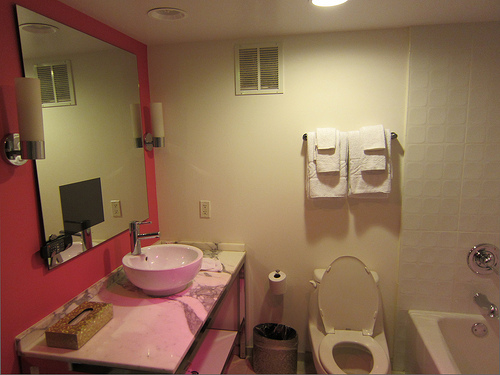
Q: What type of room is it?
A: It is a bathroom.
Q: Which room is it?
A: It is a bathroom.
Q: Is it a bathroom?
A: Yes, it is a bathroom.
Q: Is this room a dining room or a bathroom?
A: It is a bathroom.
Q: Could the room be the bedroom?
A: No, it is the bathroom.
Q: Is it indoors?
A: Yes, it is indoors.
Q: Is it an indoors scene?
A: Yes, it is indoors.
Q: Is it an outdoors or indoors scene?
A: It is indoors.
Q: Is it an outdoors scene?
A: No, it is indoors.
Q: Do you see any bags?
A: No, there are no bags.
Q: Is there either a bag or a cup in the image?
A: No, there are no bags or cups.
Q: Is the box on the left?
A: Yes, the box is on the left of the image.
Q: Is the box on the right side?
A: No, the box is on the left of the image.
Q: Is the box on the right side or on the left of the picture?
A: The box is on the left of the image.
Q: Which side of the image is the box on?
A: The box is on the left of the image.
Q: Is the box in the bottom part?
A: Yes, the box is in the bottom of the image.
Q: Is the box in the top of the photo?
A: No, the box is in the bottom of the image.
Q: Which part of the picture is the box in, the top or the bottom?
A: The box is in the bottom of the image.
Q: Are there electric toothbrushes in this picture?
A: No, there are no electric toothbrushes.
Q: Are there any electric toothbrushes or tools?
A: No, there are no electric toothbrushes or tools.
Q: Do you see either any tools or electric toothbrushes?
A: No, there are no electric toothbrushes or tools.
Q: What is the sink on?
A: The sink is on the counter.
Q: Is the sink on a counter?
A: Yes, the sink is on a counter.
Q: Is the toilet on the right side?
A: Yes, the toilet is on the right of the image.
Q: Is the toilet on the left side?
A: No, the toilet is on the right of the image.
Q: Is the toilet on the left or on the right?
A: The toilet is on the right of the image.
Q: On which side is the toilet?
A: The toilet is on the right of the image.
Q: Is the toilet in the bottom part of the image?
A: Yes, the toilet is in the bottom of the image.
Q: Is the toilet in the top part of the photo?
A: No, the toilet is in the bottom of the image.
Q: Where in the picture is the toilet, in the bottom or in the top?
A: The toilet is in the bottom of the image.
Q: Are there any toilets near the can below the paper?
A: Yes, there is a toilet near the can.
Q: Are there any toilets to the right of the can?
A: Yes, there is a toilet to the right of the can.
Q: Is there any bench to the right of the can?
A: No, there is a toilet to the right of the can.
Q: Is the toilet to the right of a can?
A: Yes, the toilet is to the right of a can.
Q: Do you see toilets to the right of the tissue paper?
A: Yes, there is a toilet to the right of the tissue paper.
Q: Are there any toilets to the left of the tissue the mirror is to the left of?
A: No, the toilet is to the right of the tissue paper.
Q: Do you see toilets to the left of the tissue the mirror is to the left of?
A: No, the toilet is to the right of the tissue paper.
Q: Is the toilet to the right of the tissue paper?
A: Yes, the toilet is to the right of the tissue paper.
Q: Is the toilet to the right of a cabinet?
A: No, the toilet is to the right of the tissue paper.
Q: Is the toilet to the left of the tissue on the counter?
A: No, the toilet is to the right of the tissue.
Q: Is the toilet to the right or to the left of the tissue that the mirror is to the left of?
A: The toilet is to the right of the tissue paper.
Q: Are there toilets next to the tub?
A: Yes, there is a toilet next to the tub.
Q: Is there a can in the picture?
A: Yes, there is a can.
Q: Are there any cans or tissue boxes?
A: Yes, there is a can.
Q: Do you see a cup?
A: No, there are no cups.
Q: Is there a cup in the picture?
A: No, there are no cups.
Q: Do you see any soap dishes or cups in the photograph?
A: No, there are no cups or soap dishes.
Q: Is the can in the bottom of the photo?
A: Yes, the can is in the bottom of the image.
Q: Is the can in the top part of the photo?
A: No, the can is in the bottom of the image.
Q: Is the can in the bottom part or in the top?
A: The can is in the bottom of the image.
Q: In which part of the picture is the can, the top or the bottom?
A: The can is in the bottom of the image.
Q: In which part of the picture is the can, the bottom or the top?
A: The can is in the bottom of the image.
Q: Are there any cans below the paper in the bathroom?
A: Yes, there is a can below the paper.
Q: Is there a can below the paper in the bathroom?
A: Yes, there is a can below the paper.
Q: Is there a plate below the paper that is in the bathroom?
A: No, there is a can below the paper.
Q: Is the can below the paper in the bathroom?
A: Yes, the can is below the paper.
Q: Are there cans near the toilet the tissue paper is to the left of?
A: Yes, there is a can near the toilet.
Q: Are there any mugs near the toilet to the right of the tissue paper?
A: No, there is a can near the toilet.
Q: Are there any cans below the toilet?
A: Yes, there is a can below the toilet.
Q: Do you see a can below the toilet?
A: Yes, there is a can below the toilet.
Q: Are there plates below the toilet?
A: No, there is a can below the toilet.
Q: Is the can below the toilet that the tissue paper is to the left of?
A: Yes, the can is below the toilet.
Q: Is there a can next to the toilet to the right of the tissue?
A: Yes, there is a can next to the toilet.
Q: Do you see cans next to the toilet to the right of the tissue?
A: Yes, there is a can next to the toilet.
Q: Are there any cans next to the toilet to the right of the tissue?
A: Yes, there is a can next to the toilet.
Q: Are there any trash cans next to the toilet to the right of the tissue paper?
A: No, there is a can next to the toilet.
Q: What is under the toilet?
A: The can is under the toilet.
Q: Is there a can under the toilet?
A: Yes, there is a can under the toilet.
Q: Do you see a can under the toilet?
A: Yes, there is a can under the toilet.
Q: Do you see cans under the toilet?
A: Yes, there is a can under the toilet.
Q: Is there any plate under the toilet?
A: No, there is a can under the toilet.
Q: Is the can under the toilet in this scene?
A: Yes, the can is under the toilet.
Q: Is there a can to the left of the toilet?
A: Yes, there is a can to the left of the toilet.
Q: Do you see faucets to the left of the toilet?
A: No, there is a can to the left of the toilet.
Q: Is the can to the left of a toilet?
A: Yes, the can is to the left of a toilet.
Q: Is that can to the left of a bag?
A: No, the can is to the left of a toilet.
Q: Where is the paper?
A: The paper is in the bathroom.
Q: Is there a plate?
A: No, there are no plates.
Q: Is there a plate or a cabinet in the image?
A: No, there are no plates or cabinets.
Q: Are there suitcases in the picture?
A: No, there are no suitcases.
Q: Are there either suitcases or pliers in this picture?
A: No, there are no suitcases or pliers.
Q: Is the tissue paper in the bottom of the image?
A: Yes, the tissue paper is in the bottom of the image.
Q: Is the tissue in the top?
A: No, the tissue is in the bottom of the image.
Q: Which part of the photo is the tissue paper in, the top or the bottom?
A: The tissue paper is in the bottom of the image.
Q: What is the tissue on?
A: The tissue is on the counter.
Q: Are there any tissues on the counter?
A: Yes, there is a tissue on the counter.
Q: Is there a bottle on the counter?
A: No, there is a tissue on the counter.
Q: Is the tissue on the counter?
A: Yes, the tissue is on the counter.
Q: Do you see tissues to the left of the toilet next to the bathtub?
A: Yes, there is a tissue to the left of the toilet.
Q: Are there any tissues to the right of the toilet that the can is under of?
A: No, the tissue is to the left of the toilet.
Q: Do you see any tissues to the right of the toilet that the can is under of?
A: No, the tissue is to the left of the toilet.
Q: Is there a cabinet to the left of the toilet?
A: No, there is a tissue to the left of the toilet.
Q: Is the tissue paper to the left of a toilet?
A: Yes, the tissue paper is to the left of a toilet.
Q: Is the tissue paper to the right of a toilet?
A: No, the tissue paper is to the left of a toilet.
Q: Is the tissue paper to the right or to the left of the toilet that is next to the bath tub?
A: The tissue paper is to the left of the toilet.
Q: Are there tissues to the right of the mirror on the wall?
A: Yes, there is a tissue to the right of the mirror.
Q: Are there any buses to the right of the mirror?
A: No, there is a tissue to the right of the mirror.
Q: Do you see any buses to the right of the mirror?
A: No, there is a tissue to the right of the mirror.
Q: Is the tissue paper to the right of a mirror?
A: Yes, the tissue paper is to the right of a mirror.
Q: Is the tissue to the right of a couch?
A: No, the tissue is to the right of a mirror.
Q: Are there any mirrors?
A: Yes, there is a mirror.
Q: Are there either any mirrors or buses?
A: Yes, there is a mirror.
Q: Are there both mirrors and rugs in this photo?
A: No, there is a mirror but no rugs.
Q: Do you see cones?
A: No, there are no cones.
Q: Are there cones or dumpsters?
A: No, there are no cones or dumpsters.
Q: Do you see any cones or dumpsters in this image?
A: No, there are no cones or dumpsters.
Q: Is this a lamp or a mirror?
A: This is a mirror.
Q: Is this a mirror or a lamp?
A: This is a mirror.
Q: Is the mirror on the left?
A: Yes, the mirror is on the left of the image.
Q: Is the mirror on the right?
A: No, the mirror is on the left of the image.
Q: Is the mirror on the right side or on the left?
A: The mirror is on the left of the image.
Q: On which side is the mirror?
A: The mirror is on the left of the image.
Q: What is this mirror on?
A: The mirror is on the wall.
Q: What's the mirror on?
A: The mirror is on the wall.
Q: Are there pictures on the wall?
A: No, there is a mirror on the wall.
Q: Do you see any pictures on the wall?
A: No, there is a mirror on the wall.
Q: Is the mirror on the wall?
A: Yes, the mirror is on the wall.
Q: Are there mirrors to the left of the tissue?
A: Yes, there is a mirror to the left of the tissue.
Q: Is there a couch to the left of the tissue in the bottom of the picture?
A: No, there is a mirror to the left of the tissue.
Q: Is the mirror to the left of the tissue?
A: Yes, the mirror is to the left of the tissue.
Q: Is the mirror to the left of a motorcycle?
A: No, the mirror is to the left of the tissue.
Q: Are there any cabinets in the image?
A: No, there are no cabinets.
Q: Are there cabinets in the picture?
A: No, there are no cabinets.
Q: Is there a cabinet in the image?
A: No, there are no cabinets.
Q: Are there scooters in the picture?
A: No, there are no scooters.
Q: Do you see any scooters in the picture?
A: No, there are no scooters.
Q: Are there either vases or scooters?
A: No, there are no scooters or vases.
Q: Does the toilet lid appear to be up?
A: Yes, the lid is up.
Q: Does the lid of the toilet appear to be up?
A: Yes, the lid is up.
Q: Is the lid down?
A: No, the lid is up.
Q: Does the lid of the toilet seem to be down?
A: No, the lid is up.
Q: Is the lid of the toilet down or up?
A: The lid is up.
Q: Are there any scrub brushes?
A: No, there are no scrub brushes.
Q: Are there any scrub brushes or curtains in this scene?
A: No, there are no scrub brushes or curtains.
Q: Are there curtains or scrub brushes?
A: No, there are no scrub brushes or curtains.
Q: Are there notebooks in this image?
A: No, there are no notebooks.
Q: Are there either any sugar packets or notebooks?
A: No, there are no notebooks or sugar packets.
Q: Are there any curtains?
A: No, there are no curtains.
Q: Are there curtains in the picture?
A: No, there are no curtains.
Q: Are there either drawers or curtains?
A: No, there are no curtains or drawers.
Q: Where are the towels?
A: The towels are in the bathroom.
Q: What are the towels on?
A: The towels are on the wall.